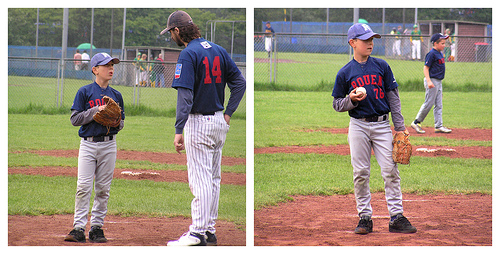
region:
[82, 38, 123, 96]
head of a person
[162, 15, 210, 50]
head of a person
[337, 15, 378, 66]
head of a person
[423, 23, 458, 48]
head of a person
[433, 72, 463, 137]
leg of a person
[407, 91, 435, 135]
leg of a person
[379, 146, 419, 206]
leg of a person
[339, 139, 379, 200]
leg of a person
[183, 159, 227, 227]
leg of a person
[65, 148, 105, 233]
leg of a person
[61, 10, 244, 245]
a young pitcher consults with a coach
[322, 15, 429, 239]
this young pitcher looks pretty savvy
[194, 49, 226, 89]
the coach's number is 14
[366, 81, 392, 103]
the young pitcher's number is 76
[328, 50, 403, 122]
the young pitcher's jersey is dark blue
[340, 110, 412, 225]
the young pitcher's pants are gray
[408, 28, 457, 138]
another player in the background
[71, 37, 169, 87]
people on the other side of the fence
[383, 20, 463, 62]
other team's pitchers warming up in the bullpen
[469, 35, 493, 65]
trash can in the background has a red lid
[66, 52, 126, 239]
Baseball player holding a brown glove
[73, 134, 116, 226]
Gray baseball pants with dirty knees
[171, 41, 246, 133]
Blue shirt over long sleeved gray shirt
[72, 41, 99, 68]
Two people walking with a green umbrella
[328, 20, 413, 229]
Baseball player holding a white baseball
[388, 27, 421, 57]
Baseball players with green shirts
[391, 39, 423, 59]
Baseball players with white pants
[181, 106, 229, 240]
Baseball player with striped pants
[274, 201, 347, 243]
Red sand on the ground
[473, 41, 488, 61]
Gray garbage can with red lid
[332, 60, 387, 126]
person holding a baseball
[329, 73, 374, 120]
baseball is in the right hand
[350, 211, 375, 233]
black shoe right foot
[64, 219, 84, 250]
black shoe right foot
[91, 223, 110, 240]
black shoe on left foot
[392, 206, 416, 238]
black shoe on left foot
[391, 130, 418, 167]
glove in left hand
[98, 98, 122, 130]
glove in left hand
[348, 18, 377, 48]
person wearing a baseball cap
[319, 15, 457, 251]
he is a baseball player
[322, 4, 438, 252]
he is a pitcher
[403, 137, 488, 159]
this is a base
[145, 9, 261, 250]
this man is a coach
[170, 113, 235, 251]
his pants are white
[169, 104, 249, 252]
his pants have pin stripes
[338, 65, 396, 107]
the text and number are red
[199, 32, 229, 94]
his jersey number is 14